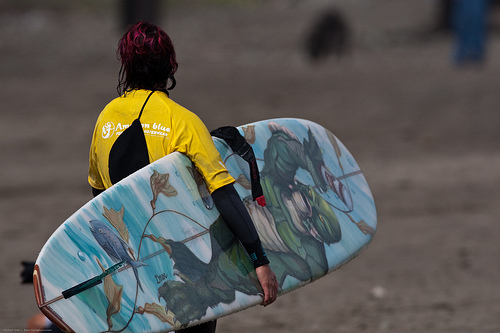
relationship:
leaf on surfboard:
[95, 197, 132, 251] [18, 108, 380, 320]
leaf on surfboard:
[97, 257, 131, 331] [21, 96, 391, 327]